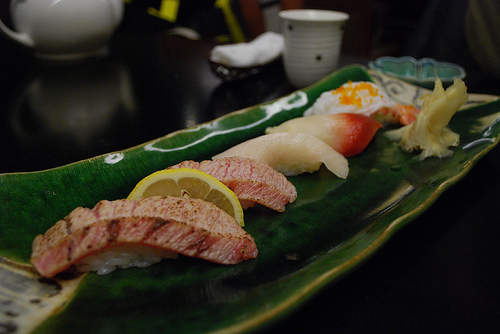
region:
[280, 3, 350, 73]
A white cup in the background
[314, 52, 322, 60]
Black spot on a cup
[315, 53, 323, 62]
Black circle on a cup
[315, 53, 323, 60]
Black circle on a white cup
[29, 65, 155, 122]
The surface is black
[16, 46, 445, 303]
Food on a plate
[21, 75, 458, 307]
Food on a green plate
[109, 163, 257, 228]
a slice of lemon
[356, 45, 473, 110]
a small glass bowl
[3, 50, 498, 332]
food on a long dish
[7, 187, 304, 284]
a piece of srimp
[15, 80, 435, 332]
a fancy sea food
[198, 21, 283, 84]
a dish with napkins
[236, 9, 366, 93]
a white glass with hole in it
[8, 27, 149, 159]
the reflection of pot on table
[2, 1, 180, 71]
a white tea pot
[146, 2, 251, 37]
a yellow and black object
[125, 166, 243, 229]
wedge of lemon with pit in center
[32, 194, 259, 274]
grilled slice of meat next to lemon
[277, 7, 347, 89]
small white plastic cup on table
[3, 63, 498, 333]
long rectangular green dish holding food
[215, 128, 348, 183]
piece of tan sushi on plate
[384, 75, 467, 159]
wedge of ginger next to sushi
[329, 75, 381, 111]
orange topping on white creme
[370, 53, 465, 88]
small green dipping bowl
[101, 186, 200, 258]
the beef is sliced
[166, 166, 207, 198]
the orange is ripe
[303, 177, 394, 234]
it is green in color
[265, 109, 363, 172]
this is sliced pineapple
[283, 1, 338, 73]
this is a cup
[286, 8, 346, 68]
the cup is white in color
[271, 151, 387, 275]
a piece of a green veggie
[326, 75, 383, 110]
yellow cheese on top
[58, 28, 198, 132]
a dark wood table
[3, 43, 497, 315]
a green dish on table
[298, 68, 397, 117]
a white sauce with cheese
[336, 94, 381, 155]
the pink end of shrimp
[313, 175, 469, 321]
the wave dish edge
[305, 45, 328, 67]
a small hole in a glass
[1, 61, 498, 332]
sushi on a shiny green plate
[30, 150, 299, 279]
slice of lemon between two pieces of sushi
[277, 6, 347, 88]
white cup with black dots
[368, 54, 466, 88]
shiny green ceramic bowl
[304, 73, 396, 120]
orange sprinkles on white condiment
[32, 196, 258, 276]
strip of grilled meat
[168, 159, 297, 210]
strip of grilled meat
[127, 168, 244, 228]
slice of lemon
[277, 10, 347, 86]
white porcelain cup with black dots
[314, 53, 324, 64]
black dot on a white cup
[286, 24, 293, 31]
black dot on a white cup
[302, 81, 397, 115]
sour cream with orange zest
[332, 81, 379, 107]
grated orange zest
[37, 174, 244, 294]
sushi on a plate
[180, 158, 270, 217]
sushi on a plate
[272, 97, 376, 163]
sushi on a plate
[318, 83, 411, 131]
sushi on a plate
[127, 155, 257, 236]
lemon on the plate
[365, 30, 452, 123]
dish on the table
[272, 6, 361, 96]
a cup on the table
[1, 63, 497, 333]
long green platter of food